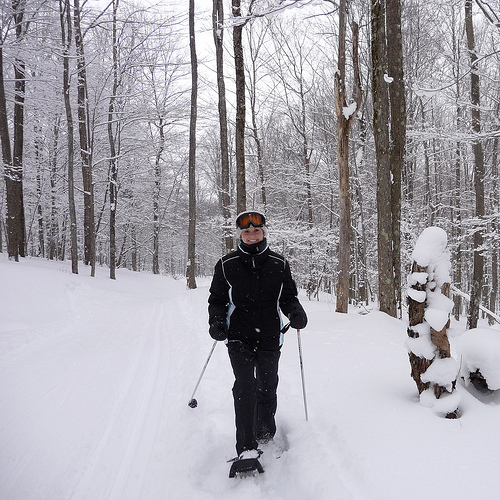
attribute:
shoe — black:
[225, 456, 264, 480]